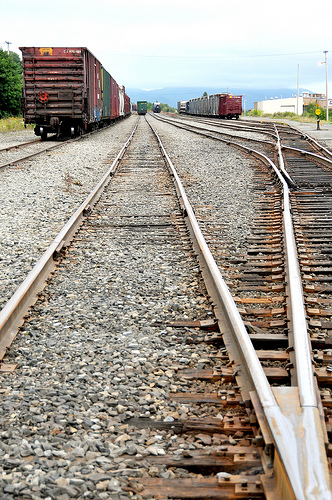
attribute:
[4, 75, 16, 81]
leaf — green